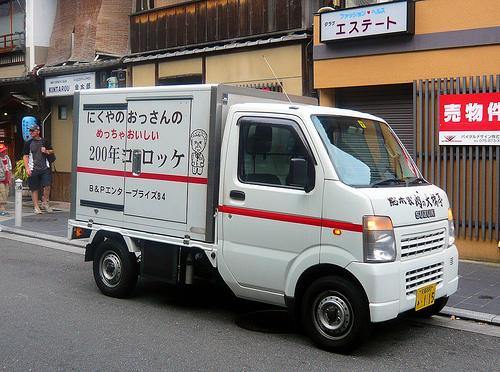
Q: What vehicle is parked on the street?
A: Truck.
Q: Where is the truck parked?
A: By sidewalk.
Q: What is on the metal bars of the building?
A: Sign.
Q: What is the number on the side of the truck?
A: 200.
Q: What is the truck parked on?
A: Street.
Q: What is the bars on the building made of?
A: Iron.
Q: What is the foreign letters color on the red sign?
A: White.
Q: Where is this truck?
A: On the road.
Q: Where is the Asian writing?
A: On the truck.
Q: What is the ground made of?
A: Pavement.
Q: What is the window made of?
A: Glass.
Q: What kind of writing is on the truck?
A: Asian.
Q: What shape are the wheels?
A: Round.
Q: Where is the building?
A: In the back.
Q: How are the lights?
A: On.